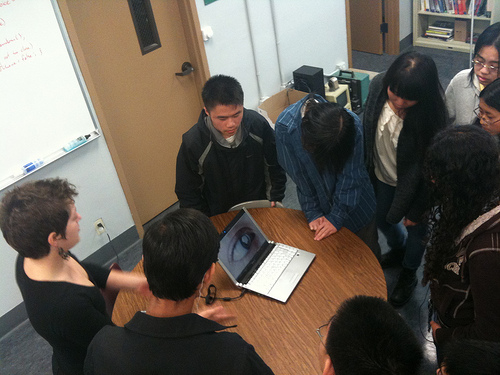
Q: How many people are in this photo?
A: Nine.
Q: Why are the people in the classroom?
A: Lesson.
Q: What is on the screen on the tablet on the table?
A: Eye.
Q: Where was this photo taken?
A: Classroom.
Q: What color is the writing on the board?
A: Red.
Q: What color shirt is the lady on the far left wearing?
A: Black.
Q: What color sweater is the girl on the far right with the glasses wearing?
A: White.